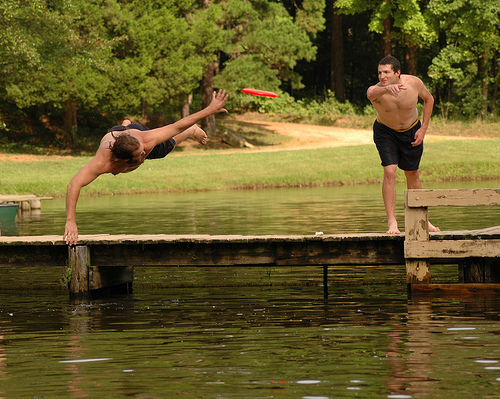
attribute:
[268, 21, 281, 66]
leaves — green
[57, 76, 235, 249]
man — jumping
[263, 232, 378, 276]
dock — wood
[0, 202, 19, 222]
boat — green 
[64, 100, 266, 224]
man — horizontal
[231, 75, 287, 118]
frisbee — red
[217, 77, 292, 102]
frisbee — red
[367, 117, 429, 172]
shorts — black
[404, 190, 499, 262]
fence — brown, wet, wooden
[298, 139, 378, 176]
grass — short, green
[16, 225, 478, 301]
dock — brown, wooden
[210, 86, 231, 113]
hand — open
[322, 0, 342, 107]
trunk — large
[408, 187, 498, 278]
paint — worn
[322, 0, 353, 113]
tree — shaded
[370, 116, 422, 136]
waistband — yellow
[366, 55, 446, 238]
man — shirtless